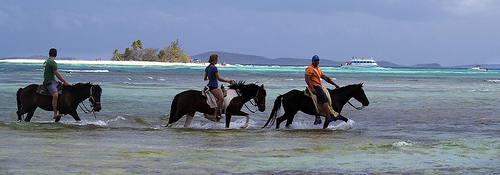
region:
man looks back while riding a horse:
[12, 40, 107, 131]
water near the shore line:
[385, 121, 495, 166]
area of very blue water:
[385, 65, 460, 75]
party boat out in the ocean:
[340, 50, 385, 70]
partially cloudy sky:
[281, 2, 436, 47]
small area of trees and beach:
[105, 30, 200, 67]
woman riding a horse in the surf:
[166, 47, 266, 132]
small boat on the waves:
[456, 55, 491, 77]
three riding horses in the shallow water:
[12, 35, 377, 141]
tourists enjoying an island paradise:
[11, 6, 476, 154]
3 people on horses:
[5, 41, 375, 133]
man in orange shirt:
[280, 50, 374, 122]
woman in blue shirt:
[161, 50, 271, 125]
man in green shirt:
[13, 40, 108, 124]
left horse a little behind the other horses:
[14, 42, 109, 127]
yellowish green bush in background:
[107, 33, 195, 65]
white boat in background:
[336, 52, 387, 72]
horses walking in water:
[13, 43, 378, 135]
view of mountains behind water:
[193, 42, 499, 74]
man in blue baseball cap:
[304, 50, 335, 118]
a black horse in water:
[269, 85, 369, 129]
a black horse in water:
[166, 80, 273, 133]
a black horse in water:
[13, 79, 105, 122]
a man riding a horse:
[271, 52, 369, 134]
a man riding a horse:
[12, 46, 106, 127]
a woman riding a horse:
[166, 52, 267, 132]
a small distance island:
[106, 39, 192, 66]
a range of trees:
[114, 39, 184, 64]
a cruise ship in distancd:
[338, 56, 380, 68]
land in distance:
[183, 49, 440, 69]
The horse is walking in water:
[266, 80, 378, 140]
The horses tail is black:
[259, 90, 283, 132]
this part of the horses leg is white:
[181, 116, 195, 132]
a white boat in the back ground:
[337, 55, 386, 66]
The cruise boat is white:
[341, 56, 378, 72]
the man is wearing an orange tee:
[304, 66, 329, 88]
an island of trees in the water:
[109, 42, 208, 65]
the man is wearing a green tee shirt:
[39, 57, 61, 84]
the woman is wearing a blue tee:
[196, 64, 226, 88]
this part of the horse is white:
[221, 88, 241, 113]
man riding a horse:
[275, 51, 365, 137]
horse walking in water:
[277, 83, 377, 130]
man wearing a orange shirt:
[297, 45, 344, 125]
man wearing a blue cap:
[299, 47, 344, 128]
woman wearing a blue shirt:
[169, 33, 266, 145]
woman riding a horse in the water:
[168, 34, 273, 128]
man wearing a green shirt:
[37, 36, 74, 121]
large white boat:
[346, 47, 391, 81]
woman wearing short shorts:
[198, 45, 241, 123]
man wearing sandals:
[32, 40, 69, 127]